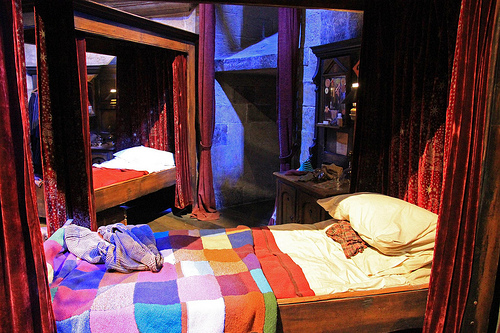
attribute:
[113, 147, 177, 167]
pillow — white, off-white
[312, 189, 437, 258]
pillow — tan, wrinkled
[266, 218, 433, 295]
sheet — wrinkled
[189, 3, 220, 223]
drape — long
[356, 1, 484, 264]
drape — red, long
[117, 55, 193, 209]
drape — red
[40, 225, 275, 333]
bedspread — multi colored, multi-colored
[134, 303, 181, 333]
square — blue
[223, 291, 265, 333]
square — orange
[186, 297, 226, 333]
square — white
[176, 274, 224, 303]
square — pink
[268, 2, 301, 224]
drape — long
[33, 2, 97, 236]
curtain — velvet, red, maroon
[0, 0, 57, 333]
curtain — velvet, red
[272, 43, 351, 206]
hutch — wood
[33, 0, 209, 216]
alcove — wood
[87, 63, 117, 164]
cabinet — wood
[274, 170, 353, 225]
nightstand — wood, small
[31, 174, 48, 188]
pajamas — plaid, red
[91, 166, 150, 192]
blanket — red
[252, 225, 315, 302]
blanket — red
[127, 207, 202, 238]
rug — moss colored